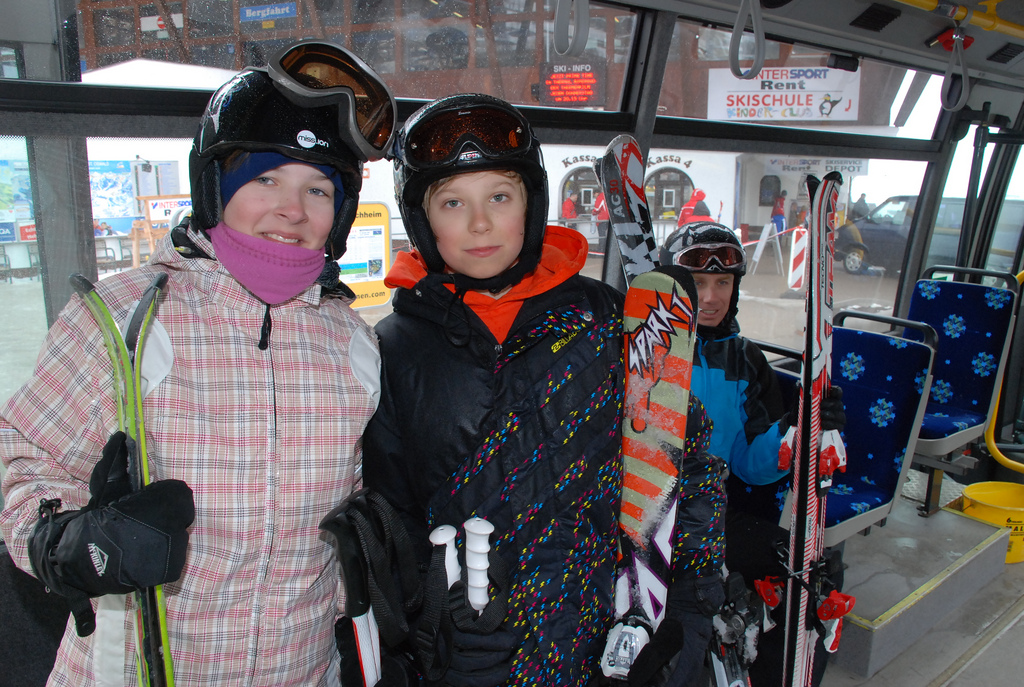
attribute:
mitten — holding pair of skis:
[25, 418, 203, 635]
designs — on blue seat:
[829, 327, 925, 434]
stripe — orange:
[626, 395, 694, 441]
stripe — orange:
[618, 274, 698, 329]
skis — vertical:
[761, 163, 861, 684]